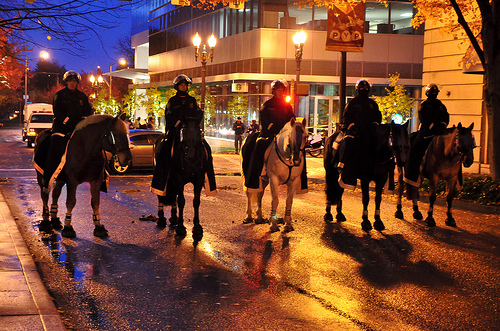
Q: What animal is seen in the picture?
A: Horse.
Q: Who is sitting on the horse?
A: Guards.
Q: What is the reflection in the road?
A: Light.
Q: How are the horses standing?
A: In straight line.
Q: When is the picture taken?
A: Night time.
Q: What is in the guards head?
A: Helmet.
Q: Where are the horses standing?
A: In the road.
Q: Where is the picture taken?
A: In the city.